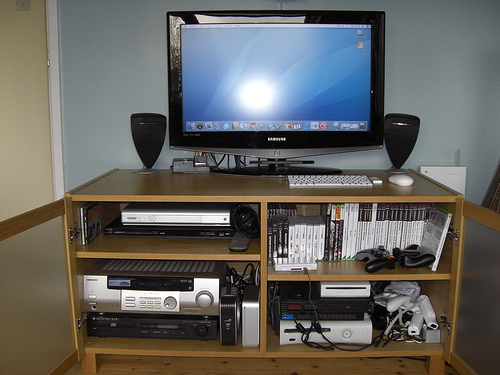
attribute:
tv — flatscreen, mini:
[172, 11, 385, 142]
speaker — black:
[131, 114, 169, 171]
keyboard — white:
[288, 176, 370, 188]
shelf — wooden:
[265, 200, 452, 273]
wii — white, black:
[419, 295, 436, 332]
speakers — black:
[382, 112, 421, 169]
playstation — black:
[275, 300, 372, 319]